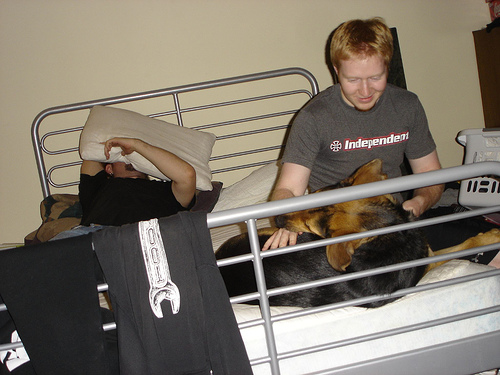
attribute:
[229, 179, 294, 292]
bed — white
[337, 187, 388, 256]
dog — brown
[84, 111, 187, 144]
pillow — white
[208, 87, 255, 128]
headboard — metal, silver, white, grey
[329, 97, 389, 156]
shirt — grey, black